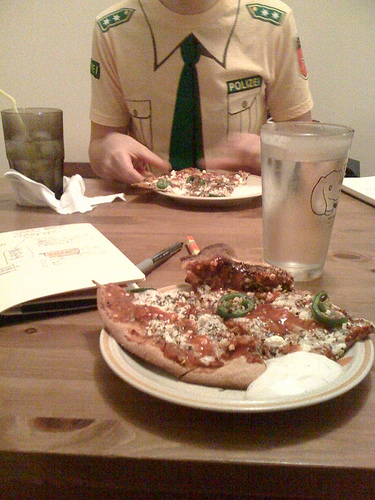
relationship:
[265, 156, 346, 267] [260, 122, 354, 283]
water inside of glass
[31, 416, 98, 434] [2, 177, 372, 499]
knot in table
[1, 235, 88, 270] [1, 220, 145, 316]
writing in notebook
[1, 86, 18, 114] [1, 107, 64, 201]
straw sticking out of glass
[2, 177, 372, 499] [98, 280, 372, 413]
table sitting beneath plate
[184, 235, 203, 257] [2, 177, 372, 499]
pen on table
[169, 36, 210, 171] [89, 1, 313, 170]
tie printed on shirt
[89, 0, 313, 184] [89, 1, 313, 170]
man has shirt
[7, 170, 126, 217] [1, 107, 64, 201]
napkin near glass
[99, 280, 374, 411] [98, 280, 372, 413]
plate on plate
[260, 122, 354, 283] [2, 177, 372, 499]
glass sitting on table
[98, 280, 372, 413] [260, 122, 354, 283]
plate near glass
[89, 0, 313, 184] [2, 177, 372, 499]
man sitting at table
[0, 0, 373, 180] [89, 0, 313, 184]
wall behind man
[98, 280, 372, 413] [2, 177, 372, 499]
plate sitting on table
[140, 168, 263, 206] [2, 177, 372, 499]
plate sitting on table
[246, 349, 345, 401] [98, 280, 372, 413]
sauce on plate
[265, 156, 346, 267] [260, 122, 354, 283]
water in glass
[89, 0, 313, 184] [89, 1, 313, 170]
man wearing shirt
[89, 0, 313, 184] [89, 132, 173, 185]
man has hand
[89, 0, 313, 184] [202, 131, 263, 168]
man has hand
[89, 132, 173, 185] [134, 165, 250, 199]
hand near pizza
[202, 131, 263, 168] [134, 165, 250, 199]
hand near pizza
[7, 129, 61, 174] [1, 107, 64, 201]
ice inside of glass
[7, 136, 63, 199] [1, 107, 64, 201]
water in glass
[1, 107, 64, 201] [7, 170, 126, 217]
glass resting on napkin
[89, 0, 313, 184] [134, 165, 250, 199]
man eating pizza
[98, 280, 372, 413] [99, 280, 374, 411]
plate has plate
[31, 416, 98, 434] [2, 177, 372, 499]
knot on table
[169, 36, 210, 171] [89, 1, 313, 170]
tie drawn on shirt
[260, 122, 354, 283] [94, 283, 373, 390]
glass near pizza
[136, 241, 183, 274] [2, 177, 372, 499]
pen on table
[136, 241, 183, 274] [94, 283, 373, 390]
pen near pizza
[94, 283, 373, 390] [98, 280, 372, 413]
pizza on plate